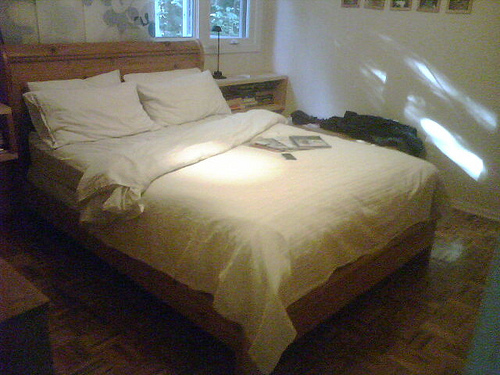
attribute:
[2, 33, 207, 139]
headboard — light, brown, wooden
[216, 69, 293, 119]
night stand — beige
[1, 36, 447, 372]
bed — side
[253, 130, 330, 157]
books — kept in the bed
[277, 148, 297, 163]
remote control — on bed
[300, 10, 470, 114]
white wall — in bedroom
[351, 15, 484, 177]
sunlight — wall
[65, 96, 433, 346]
cover — white 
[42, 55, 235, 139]
pillows — group 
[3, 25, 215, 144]
headboard — brown 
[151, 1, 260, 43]
window — side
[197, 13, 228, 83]
lamp — side